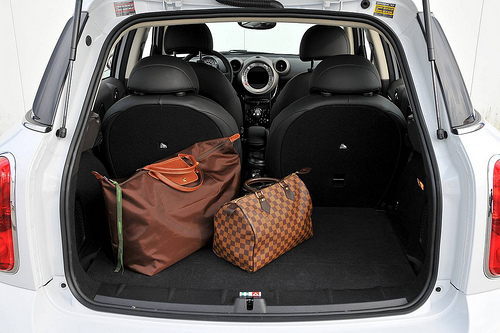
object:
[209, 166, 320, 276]
bag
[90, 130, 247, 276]
purse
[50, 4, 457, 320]
trunk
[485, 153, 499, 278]
light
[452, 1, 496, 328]
right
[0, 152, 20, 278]
tail light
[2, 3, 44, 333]
left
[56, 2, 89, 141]
latch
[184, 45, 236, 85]
steering wheel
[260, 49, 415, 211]
seat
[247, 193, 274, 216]
desigs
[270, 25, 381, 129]
passenger seat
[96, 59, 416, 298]
back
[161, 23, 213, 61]
head rest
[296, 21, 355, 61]
head rest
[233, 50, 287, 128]
console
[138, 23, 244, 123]
front seats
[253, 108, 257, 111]
buttons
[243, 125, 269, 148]
gear shift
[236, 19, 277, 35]
mirror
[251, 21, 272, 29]
rear view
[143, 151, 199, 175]
handles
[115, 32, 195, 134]
left side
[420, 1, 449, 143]
rod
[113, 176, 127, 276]
strip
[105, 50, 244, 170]
seat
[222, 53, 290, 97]
dashboard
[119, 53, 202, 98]
headrest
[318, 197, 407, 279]
floor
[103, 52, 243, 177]
back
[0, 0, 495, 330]
car